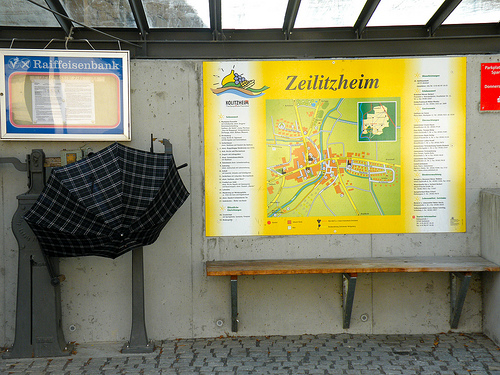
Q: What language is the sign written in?
A: German.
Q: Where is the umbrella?
A: Next to the bench.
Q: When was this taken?
A: Daytime.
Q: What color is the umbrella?
A: Black and white.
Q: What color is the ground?
A: Grey.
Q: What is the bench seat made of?
A: Wood.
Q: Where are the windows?
A: On the ceiling.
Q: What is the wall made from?
A: Concrete.